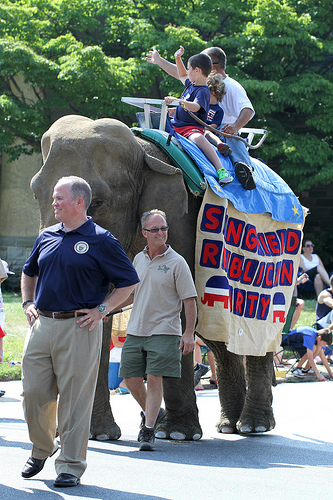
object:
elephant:
[27, 112, 300, 442]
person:
[144, 47, 257, 195]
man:
[19, 174, 141, 490]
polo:
[17, 214, 141, 319]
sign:
[190, 177, 311, 359]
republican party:
[198, 201, 305, 319]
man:
[117, 208, 198, 451]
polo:
[119, 245, 198, 340]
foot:
[154, 413, 204, 441]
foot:
[234, 403, 275, 435]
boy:
[278, 325, 332, 383]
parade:
[13, 43, 332, 491]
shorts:
[116, 332, 183, 381]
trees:
[0, 0, 332, 226]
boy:
[163, 44, 234, 190]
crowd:
[274, 236, 330, 382]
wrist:
[94, 302, 110, 318]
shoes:
[56, 464, 82, 489]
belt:
[34, 307, 90, 319]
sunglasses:
[142, 223, 168, 235]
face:
[146, 214, 167, 249]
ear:
[139, 153, 189, 225]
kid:
[197, 69, 232, 158]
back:
[129, 123, 301, 205]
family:
[144, 38, 275, 189]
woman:
[295, 236, 331, 304]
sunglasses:
[302, 242, 316, 251]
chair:
[296, 269, 331, 303]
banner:
[180, 191, 312, 360]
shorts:
[171, 120, 202, 138]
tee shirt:
[169, 75, 216, 128]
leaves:
[64, 74, 71, 84]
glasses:
[143, 224, 169, 234]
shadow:
[85, 424, 332, 473]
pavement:
[0, 379, 332, 494]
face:
[50, 177, 70, 223]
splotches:
[62, 201, 76, 217]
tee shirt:
[280, 328, 325, 354]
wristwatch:
[98, 301, 108, 319]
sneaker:
[137, 424, 157, 454]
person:
[298, 239, 331, 306]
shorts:
[299, 267, 318, 297]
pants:
[18, 314, 103, 476]